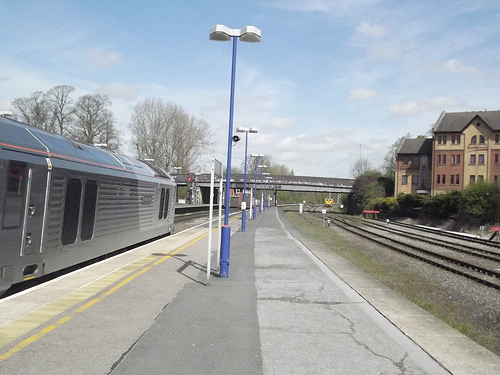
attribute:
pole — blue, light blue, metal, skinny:
[218, 37, 238, 277]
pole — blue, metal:
[242, 133, 252, 231]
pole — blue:
[251, 159, 259, 219]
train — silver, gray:
[1, 115, 179, 297]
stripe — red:
[0, 142, 155, 176]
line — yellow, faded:
[0, 217, 217, 367]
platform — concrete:
[1, 204, 454, 374]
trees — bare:
[225, 156, 295, 175]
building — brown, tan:
[431, 111, 500, 196]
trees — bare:
[128, 97, 213, 173]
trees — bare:
[7, 84, 129, 153]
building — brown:
[393, 137, 432, 195]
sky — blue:
[0, 2, 500, 178]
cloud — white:
[380, 95, 462, 117]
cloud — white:
[68, 44, 120, 67]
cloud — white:
[354, 21, 392, 41]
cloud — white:
[277, 134, 355, 156]